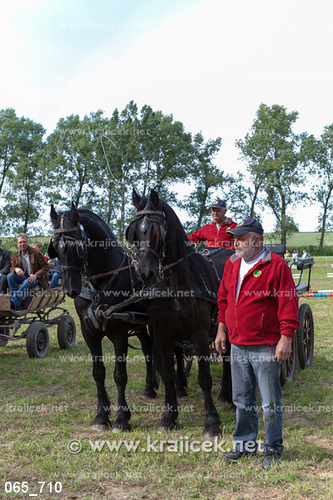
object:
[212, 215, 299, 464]
man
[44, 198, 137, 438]
horse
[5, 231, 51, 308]
man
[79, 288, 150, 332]
hardware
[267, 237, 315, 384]
carriage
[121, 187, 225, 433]
horse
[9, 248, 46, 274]
jacket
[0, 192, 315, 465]
people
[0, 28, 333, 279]
park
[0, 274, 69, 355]
hardware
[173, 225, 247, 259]
rail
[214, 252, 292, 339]
coat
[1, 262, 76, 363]
wagon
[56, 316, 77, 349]
tire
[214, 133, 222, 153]
leave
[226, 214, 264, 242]
hat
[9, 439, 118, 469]
grass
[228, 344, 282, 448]
jean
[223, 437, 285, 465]
shoe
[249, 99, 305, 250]
tree